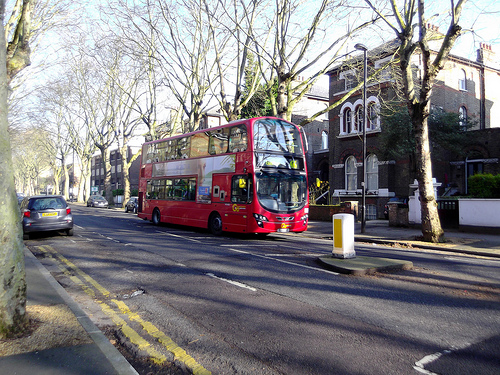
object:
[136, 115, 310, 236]
bus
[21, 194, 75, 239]
car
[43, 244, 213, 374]
line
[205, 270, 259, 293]
line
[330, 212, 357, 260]
median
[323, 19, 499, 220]
building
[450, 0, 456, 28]
branch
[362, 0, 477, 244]
tree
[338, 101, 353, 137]
window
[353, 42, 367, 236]
light post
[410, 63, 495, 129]
shadow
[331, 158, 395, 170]
trim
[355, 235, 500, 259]
curb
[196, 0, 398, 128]
tree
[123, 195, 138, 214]
car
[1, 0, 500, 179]
sky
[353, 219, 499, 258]
sidewalk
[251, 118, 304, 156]
window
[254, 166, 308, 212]
window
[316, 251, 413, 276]
platform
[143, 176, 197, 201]
window